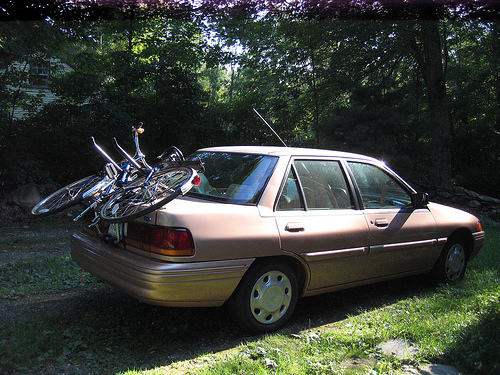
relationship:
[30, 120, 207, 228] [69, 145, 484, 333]
bicycles on back of car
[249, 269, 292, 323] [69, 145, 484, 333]
rim on tire of car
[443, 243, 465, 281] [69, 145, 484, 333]
rim on tire of car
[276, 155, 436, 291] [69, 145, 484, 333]
side doors on side of car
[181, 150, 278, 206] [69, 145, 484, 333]
rear window on back of car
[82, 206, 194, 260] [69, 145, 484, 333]
tail lights on back of car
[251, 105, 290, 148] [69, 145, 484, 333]
antennae on top of car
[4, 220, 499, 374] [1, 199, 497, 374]
grass growing from ground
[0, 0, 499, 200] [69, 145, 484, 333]
trees behind car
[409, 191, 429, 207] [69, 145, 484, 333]
sideview mirror on side of car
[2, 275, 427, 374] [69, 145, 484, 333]
shadow on bottom of car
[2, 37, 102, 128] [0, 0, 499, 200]
house behind trees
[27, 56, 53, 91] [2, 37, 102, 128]
window on side of house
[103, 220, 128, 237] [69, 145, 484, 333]
license plate on back of car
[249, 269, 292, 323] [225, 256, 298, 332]
rim inside of tire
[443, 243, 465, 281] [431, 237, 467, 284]
rim inside of tire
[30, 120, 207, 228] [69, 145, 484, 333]
bicycles mounted on car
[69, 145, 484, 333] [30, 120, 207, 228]
car carrying bicycles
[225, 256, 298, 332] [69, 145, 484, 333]
tire on rear of car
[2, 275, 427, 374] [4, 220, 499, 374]
shadow on top of grass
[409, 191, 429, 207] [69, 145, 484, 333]
sideview mirror on exterior of car